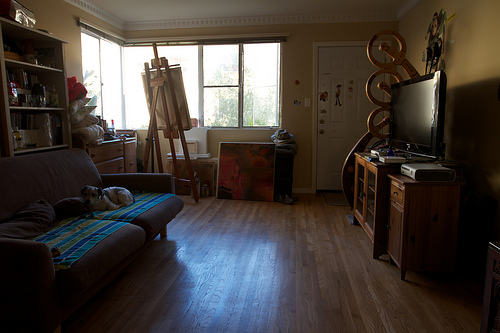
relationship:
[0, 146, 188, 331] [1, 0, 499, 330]
couch in living room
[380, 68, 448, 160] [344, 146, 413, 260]
tv on stand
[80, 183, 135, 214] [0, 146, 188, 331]
dog on couch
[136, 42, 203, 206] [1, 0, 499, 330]
art easel in living room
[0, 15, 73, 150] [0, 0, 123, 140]
bookcase by wall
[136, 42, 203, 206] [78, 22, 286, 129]
art easel beside windows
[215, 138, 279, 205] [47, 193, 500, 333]
painting on floor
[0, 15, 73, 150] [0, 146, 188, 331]
bookcase behind couch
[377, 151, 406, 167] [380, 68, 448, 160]
game console by tv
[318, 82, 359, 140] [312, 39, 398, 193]
stickers on door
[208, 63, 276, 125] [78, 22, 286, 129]
trees outside windows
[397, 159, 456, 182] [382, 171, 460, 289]
xbox on cabinet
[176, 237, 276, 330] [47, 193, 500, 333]
sunlight on floor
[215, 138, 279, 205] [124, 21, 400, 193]
painting against wall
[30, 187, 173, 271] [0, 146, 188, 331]
cloth on couch